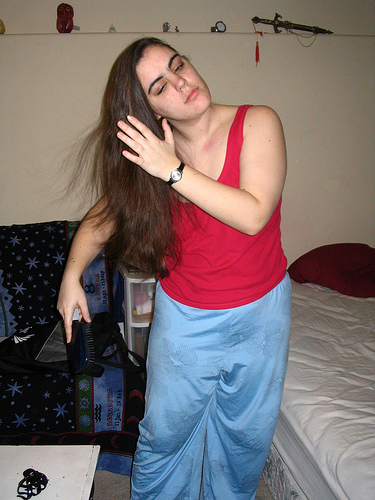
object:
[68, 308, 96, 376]
brush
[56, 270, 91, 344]
hand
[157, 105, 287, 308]
shirt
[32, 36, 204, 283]
hair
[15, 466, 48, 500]
tape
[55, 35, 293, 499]
person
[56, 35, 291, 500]
woman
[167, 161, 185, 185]
wristwatch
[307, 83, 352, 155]
wall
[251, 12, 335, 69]
sword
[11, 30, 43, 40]
shelf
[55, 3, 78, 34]
owl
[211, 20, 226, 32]
clock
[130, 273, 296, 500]
pants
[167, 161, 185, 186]
watch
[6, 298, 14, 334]
towel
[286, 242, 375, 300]
pillow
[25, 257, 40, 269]
stars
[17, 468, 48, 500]
hair clip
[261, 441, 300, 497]
box spring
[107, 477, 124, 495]
floor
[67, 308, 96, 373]
hairbrush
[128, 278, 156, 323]
storage unit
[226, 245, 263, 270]
tank top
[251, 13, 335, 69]
knife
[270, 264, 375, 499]
sheet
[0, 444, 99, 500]
table top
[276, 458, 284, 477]
flowers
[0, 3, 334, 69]
collectables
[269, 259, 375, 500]
pad cover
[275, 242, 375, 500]
bed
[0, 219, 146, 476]
blanket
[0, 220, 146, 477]
chair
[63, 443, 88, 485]
table